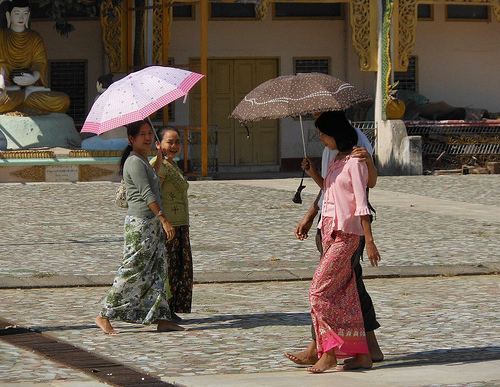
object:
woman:
[297, 112, 381, 375]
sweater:
[316, 157, 376, 234]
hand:
[352, 147, 369, 161]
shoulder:
[346, 148, 367, 168]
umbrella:
[236, 70, 369, 165]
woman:
[99, 123, 164, 332]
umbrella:
[81, 65, 207, 160]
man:
[307, 107, 382, 177]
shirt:
[316, 123, 373, 176]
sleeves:
[352, 162, 374, 221]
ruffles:
[230, 101, 367, 123]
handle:
[297, 113, 311, 159]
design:
[242, 83, 361, 105]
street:
[3, 176, 499, 385]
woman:
[147, 130, 192, 333]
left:
[3, 6, 260, 384]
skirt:
[311, 217, 370, 354]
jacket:
[119, 157, 164, 221]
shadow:
[177, 308, 322, 329]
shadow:
[371, 343, 499, 370]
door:
[188, 57, 282, 173]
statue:
[2, 2, 107, 184]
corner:
[2, 4, 202, 241]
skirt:
[106, 215, 177, 325]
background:
[1, 4, 496, 171]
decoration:
[348, 0, 422, 117]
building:
[56, 4, 498, 170]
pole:
[196, 8, 211, 171]